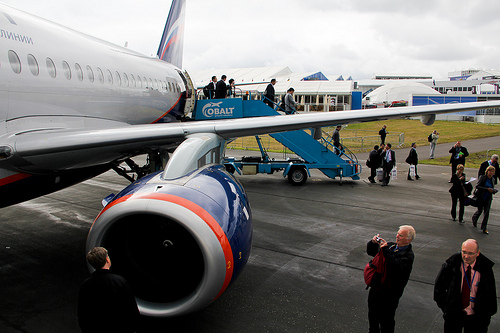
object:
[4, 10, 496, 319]
plane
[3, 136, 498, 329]
runway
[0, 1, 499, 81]
sky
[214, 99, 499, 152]
grass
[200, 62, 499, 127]
buildings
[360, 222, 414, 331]
people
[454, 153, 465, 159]
folder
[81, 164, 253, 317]
engine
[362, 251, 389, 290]
backpack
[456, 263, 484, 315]
shirt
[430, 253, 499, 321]
jacket